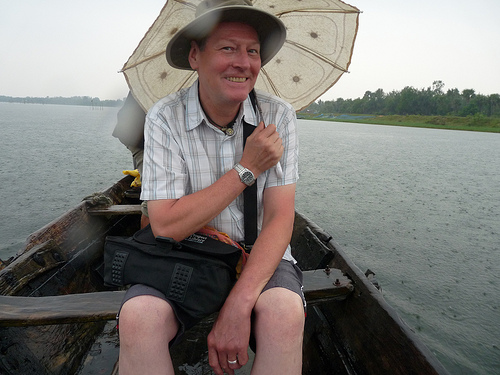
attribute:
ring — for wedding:
[226, 357, 238, 365]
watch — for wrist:
[232, 162, 256, 188]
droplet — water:
[99, 79, 141, 143]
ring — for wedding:
[217, 345, 249, 367]